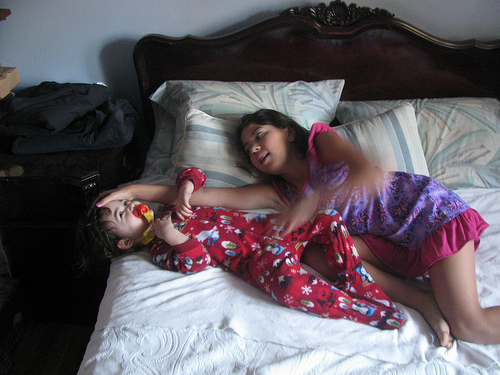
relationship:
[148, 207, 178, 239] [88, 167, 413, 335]
hand of baby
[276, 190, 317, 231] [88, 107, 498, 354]
hand of girl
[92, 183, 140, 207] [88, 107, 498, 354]
hand of girl